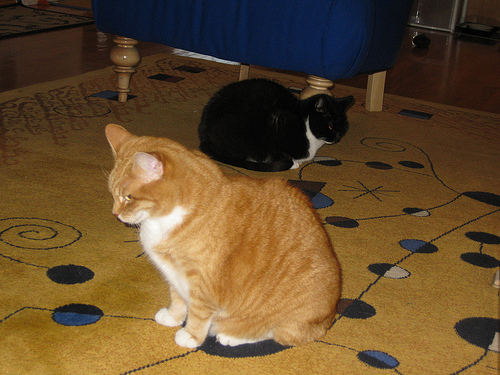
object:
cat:
[197, 77, 358, 172]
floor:
[12, 36, 493, 367]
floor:
[4, 6, 494, 373]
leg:
[110, 38, 139, 103]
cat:
[101, 122, 343, 348]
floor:
[5, 170, 94, 206]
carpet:
[369, 206, 483, 366]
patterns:
[367, 234, 437, 282]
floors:
[470, 53, 495, 84]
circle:
[51, 303, 103, 326]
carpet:
[11, 210, 117, 351]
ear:
[103, 123, 134, 156]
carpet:
[19, 110, 97, 188]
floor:
[17, 157, 106, 338]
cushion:
[91, 0, 413, 111]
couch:
[116, 3, 197, 32]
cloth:
[332, 17, 390, 62]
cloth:
[257, 19, 298, 49]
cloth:
[303, 13, 361, 53]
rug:
[27, 233, 130, 338]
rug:
[333, 152, 385, 202]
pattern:
[363, 220, 482, 287]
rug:
[361, 137, 488, 358]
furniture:
[102, 12, 406, 103]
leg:
[106, 34, 140, 101]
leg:
[305, 72, 332, 97]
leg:
[368, 70, 386, 109]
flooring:
[429, 60, 476, 90]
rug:
[356, 221, 412, 319]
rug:
[353, 211, 463, 350]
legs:
[105, 34, 397, 119]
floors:
[9, 29, 70, 96]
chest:
[138, 223, 186, 306]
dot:
[366, 263, 412, 280]